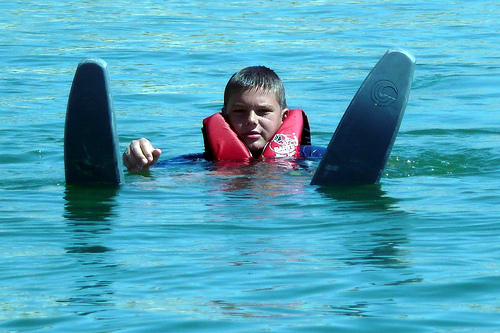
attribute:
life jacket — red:
[198, 107, 305, 162]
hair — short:
[219, 65, 290, 122]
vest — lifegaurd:
[202, 102, 312, 167]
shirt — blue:
[150, 134, 332, 171]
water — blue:
[374, 216, 487, 306]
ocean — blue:
[1, 0, 498, 327]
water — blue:
[2, 2, 497, 331]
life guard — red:
[195, 111, 306, 166]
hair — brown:
[223, 66, 285, 111]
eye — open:
[253, 107, 270, 114]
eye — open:
[229, 109, 245, 114]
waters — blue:
[7, 179, 497, 329]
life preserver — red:
[185, 95, 313, 170]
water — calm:
[7, 119, 494, 325]